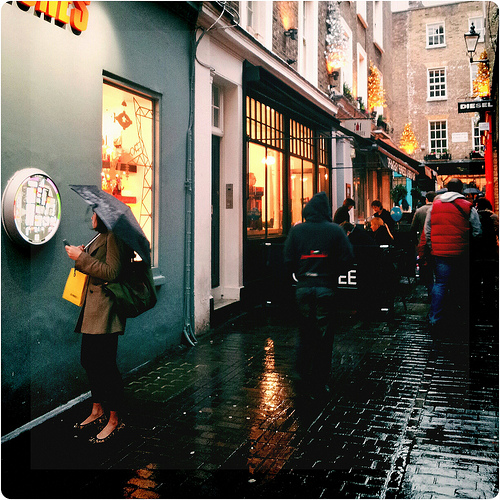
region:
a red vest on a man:
[428, 195, 473, 257]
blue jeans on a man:
[425, 259, 458, 325]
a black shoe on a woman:
[85, 417, 125, 447]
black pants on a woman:
[77, 334, 131, 412]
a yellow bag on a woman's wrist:
[60, 266, 89, 310]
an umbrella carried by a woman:
[65, 183, 154, 265]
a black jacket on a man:
[284, 190, 353, 286]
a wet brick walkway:
[5, 331, 496, 497]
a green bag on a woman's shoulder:
[104, 243, 161, 318]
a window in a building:
[424, 62, 446, 105]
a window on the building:
[428, 68, 445, 98]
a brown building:
[396, 13, 481, 156]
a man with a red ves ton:
[428, 180, 480, 321]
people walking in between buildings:
[284, 162, 484, 347]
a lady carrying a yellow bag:
[53, 170, 146, 449]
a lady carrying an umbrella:
[61, 173, 136, 438]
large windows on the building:
[246, 107, 333, 221]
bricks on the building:
[268, 22, 301, 58]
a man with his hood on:
[273, 191, 360, 380]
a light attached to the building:
[460, 22, 485, 67]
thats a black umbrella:
[71, 179, 160, 268]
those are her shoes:
[67, 419, 131, 446]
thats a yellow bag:
[56, 266, 96, 308]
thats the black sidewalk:
[5, 284, 499, 492]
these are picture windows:
[246, 142, 336, 237]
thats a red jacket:
[427, 203, 474, 258]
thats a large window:
[97, 70, 164, 285]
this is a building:
[389, 0, 497, 161]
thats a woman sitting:
[364, 217, 394, 275]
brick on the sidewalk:
[331, 419, 356, 437]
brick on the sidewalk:
[336, 468, 371, 483]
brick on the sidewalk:
[425, 476, 457, 488]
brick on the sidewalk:
[357, 421, 397, 439]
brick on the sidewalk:
[212, 467, 247, 499]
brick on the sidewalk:
[387, 429, 428, 444]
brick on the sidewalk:
[287, 442, 317, 454]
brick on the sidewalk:
[360, 472, 407, 489]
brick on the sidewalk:
[303, 413, 330, 433]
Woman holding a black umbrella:
[61, 177, 163, 263]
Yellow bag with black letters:
[61, 264, 93, 309]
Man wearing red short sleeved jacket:
[426, 178, 481, 260]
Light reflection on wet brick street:
[235, 324, 312, 474]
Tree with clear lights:
[396, 120, 425, 162]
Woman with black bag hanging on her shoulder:
[67, 209, 160, 335]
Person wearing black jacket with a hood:
[276, 188, 356, 296]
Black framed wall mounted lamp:
[460, 19, 492, 73]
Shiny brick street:
[329, 349, 466, 466]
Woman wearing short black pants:
[67, 183, 154, 453]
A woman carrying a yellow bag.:
[60, 257, 88, 307]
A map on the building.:
[2, 165, 62, 248]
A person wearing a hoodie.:
[281, 190, 356, 405]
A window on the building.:
[102, 80, 153, 267]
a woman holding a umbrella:
[70, 174, 141, 267]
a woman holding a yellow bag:
[59, 264, 96, 308]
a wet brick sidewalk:
[287, 351, 487, 494]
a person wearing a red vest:
[428, 192, 464, 261]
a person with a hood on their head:
[300, 187, 332, 228]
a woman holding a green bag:
[95, 258, 166, 324]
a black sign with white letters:
[457, 95, 497, 113]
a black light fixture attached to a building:
[462, 15, 491, 70]